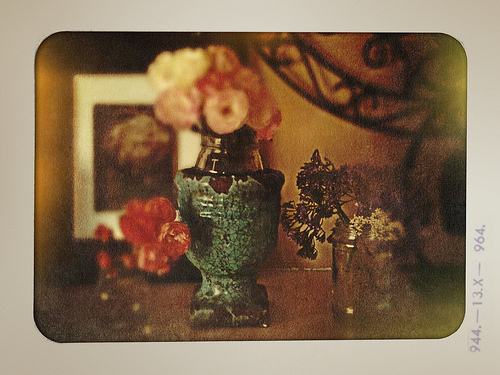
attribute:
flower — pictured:
[202, 85, 252, 137]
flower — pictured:
[276, 149, 351, 260]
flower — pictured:
[308, 171, 374, 223]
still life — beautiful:
[32, 28, 465, 338]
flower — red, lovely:
[133, 244, 172, 278]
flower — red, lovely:
[155, 218, 190, 260]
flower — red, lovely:
[141, 192, 176, 224]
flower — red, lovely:
[120, 195, 145, 217]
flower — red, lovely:
[114, 210, 136, 239]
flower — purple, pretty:
[280, 195, 335, 259]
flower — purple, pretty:
[300, 145, 351, 218]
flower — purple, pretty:
[350, 158, 432, 228]